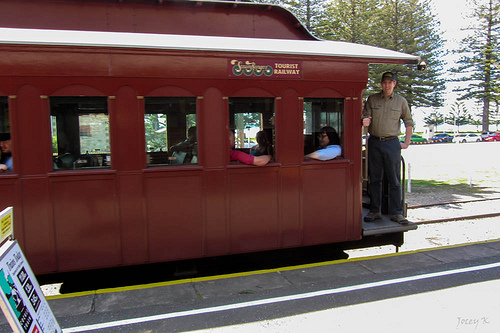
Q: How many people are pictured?
A: 6.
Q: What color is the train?
A: Red.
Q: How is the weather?
A: Sunny.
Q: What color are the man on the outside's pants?
A: Black.